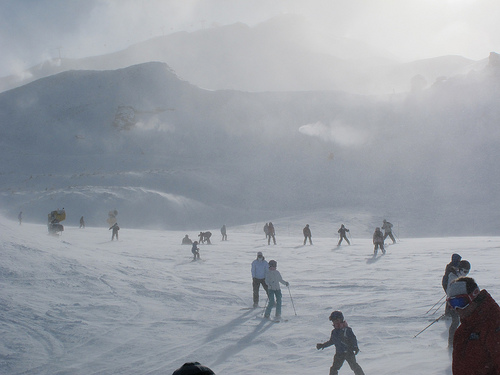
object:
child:
[315, 311, 362, 374]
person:
[251, 251, 268, 309]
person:
[335, 223, 350, 247]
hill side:
[0, 45, 74, 89]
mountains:
[6, 14, 499, 232]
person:
[202, 231, 213, 245]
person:
[303, 224, 314, 245]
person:
[265, 221, 277, 245]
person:
[381, 219, 397, 244]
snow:
[297, 117, 370, 146]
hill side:
[0, 64, 436, 214]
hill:
[127, 187, 202, 228]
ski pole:
[287, 286, 298, 317]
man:
[446, 276, 499, 374]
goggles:
[446, 292, 474, 309]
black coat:
[451, 287, 500, 374]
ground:
[391, 124, 418, 166]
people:
[445, 276, 500, 374]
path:
[12, 265, 172, 373]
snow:
[271, 50, 298, 104]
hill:
[0, 57, 389, 150]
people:
[264, 260, 290, 322]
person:
[264, 260, 288, 322]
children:
[191, 240, 202, 261]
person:
[220, 224, 227, 241]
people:
[372, 227, 387, 256]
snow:
[103, 8, 161, 67]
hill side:
[48, 14, 495, 92]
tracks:
[12, 271, 245, 375]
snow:
[8, 175, 205, 206]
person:
[18, 211, 24, 226]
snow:
[308, 241, 415, 266]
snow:
[129, 108, 174, 135]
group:
[3, 201, 404, 314]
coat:
[264, 270, 286, 291]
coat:
[251, 257, 269, 280]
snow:
[14, 244, 173, 344]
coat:
[264, 267, 290, 287]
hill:
[0, 221, 500, 375]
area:
[0, 217, 498, 373]